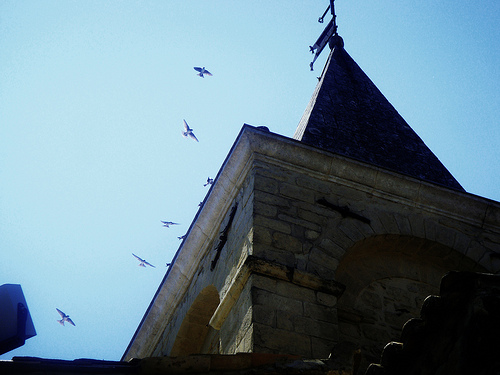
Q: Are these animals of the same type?
A: Yes, all the animals are birds.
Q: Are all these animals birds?
A: Yes, all the animals are birds.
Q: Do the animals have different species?
A: No, all the animals are birds.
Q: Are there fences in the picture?
A: No, there are no fences.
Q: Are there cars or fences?
A: No, there are no fences or cars.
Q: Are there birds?
A: Yes, there is a bird.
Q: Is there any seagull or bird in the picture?
A: Yes, there is a bird.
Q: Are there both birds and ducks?
A: No, there is a bird but no ducks.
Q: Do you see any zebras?
A: No, there are no zebras.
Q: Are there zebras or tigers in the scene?
A: No, there are no zebras or tigers.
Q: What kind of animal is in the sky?
A: The animal is a bird.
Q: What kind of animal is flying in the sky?
A: The animal is a bird.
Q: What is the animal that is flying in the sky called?
A: The animal is a bird.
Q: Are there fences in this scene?
A: No, there are no fences.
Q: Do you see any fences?
A: No, there are no fences.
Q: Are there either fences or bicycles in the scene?
A: No, there are no fences or bicycles.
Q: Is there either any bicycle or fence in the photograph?
A: No, there are no fences or bicycles.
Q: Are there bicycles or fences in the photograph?
A: No, there are no fences or bicycles.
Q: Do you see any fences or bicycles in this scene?
A: No, there are no fences or bicycles.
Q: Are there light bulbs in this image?
A: No, there are no light bulbs.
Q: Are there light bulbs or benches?
A: No, there are no light bulbs or benches.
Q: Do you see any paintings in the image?
A: No, there are no paintings.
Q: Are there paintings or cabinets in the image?
A: No, there are no paintings or cabinets.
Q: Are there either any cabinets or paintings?
A: No, there are no paintings or cabinets.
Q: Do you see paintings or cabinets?
A: No, there are no paintings or cabinets.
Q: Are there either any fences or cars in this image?
A: No, there are no cars or fences.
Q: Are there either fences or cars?
A: No, there are no cars or fences.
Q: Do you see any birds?
A: Yes, there is a bird.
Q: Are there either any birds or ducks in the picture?
A: Yes, there is a bird.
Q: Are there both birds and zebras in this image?
A: No, there is a bird but no zebras.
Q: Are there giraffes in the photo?
A: No, there are no giraffes.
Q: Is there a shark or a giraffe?
A: No, there are no giraffes or sharks.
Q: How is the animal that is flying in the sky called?
A: The animal is a bird.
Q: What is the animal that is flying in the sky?
A: The animal is a bird.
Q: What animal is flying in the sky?
A: The animal is a bird.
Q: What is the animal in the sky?
A: The animal is a bird.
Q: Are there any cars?
A: No, there are no cars.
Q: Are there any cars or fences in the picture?
A: No, there are no cars or fences.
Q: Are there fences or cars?
A: No, there are no cars or fences.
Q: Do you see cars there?
A: No, there are no cars.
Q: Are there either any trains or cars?
A: No, there are no cars or trains.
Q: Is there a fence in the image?
A: No, there are no fences.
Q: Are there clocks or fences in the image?
A: No, there are no fences or clocks.